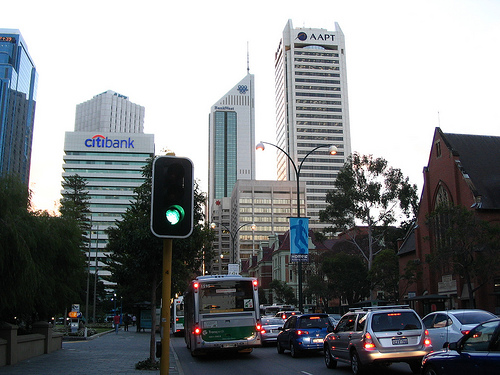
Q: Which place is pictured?
A: It is a city.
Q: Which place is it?
A: It is a city.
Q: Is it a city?
A: Yes, it is a city.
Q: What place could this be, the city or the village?
A: It is the city.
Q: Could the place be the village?
A: No, it is the city.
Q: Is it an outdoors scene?
A: Yes, it is outdoors.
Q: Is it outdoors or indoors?
A: It is outdoors.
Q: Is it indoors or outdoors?
A: It is outdoors.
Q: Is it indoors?
A: No, it is outdoors.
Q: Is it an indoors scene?
A: No, it is outdoors.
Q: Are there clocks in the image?
A: No, there are no clocks.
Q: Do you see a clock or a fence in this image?
A: No, there are no clocks or fences.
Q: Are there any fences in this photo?
A: No, there are no fences.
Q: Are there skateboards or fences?
A: No, there are no fences or skateboards.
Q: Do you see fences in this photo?
A: No, there are no fences.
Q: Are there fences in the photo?
A: No, there are no fences.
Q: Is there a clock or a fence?
A: No, there are no fences or clocks.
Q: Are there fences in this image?
A: No, there are no fences.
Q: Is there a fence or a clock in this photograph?
A: No, there are no fences or clocks.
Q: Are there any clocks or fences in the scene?
A: No, there are no fences or clocks.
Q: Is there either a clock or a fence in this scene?
A: No, there are no fences or clocks.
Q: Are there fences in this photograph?
A: No, there are no fences.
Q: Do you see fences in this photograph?
A: No, there are no fences.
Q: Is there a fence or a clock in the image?
A: No, there are no fences or clocks.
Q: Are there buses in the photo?
A: Yes, there is a bus.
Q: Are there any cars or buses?
A: Yes, there is a bus.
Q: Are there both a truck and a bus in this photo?
A: No, there is a bus but no trucks.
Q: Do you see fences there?
A: No, there are no fences.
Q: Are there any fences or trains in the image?
A: No, there are no fences or trains.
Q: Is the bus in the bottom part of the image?
A: Yes, the bus is in the bottom of the image.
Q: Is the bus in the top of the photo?
A: No, the bus is in the bottom of the image.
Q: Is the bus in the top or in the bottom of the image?
A: The bus is in the bottom of the image.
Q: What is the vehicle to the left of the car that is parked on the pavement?
A: The vehicle is a bus.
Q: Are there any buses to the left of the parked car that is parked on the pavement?
A: Yes, there is a bus to the left of the car.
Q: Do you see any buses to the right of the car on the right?
A: No, the bus is to the left of the car.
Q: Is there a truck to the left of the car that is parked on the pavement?
A: No, there is a bus to the left of the car.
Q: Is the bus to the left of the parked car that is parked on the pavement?
A: Yes, the bus is to the left of the car.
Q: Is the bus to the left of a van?
A: No, the bus is to the left of the car.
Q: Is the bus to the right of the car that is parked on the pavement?
A: No, the bus is to the left of the car.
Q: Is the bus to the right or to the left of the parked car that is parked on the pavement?
A: The bus is to the left of the car.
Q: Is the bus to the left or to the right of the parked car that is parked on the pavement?
A: The bus is to the left of the car.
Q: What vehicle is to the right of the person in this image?
A: The vehicle is a bus.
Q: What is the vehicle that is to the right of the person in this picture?
A: The vehicle is a bus.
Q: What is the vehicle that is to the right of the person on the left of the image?
A: The vehicle is a bus.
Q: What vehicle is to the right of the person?
A: The vehicle is a bus.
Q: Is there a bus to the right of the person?
A: Yes, there is a bus to the right of the person.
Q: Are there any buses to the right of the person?
A: Yes, there is a bus to the right of the person.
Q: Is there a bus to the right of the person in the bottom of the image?
A: Yes, there is a bus to the right of the person.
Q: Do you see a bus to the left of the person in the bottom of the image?
A: No, the bus is to the right of the person.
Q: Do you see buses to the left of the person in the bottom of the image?
A: No, the bus is to the right of the person.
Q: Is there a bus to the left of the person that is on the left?
A: No, the bus is to the right of the person.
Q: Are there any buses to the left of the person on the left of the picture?
A: No, the bus is to the right of the person.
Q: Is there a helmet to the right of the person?
A: No, there is a bus to the right of the person.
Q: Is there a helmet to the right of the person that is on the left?
A: No, there is a bus to the right of the person.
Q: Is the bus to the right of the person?
A: Yes, the bus is to the right of the person.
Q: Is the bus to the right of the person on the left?
A: Yes, the bus is to the right of the person.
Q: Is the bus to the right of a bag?
A: No, the bus is to the right of the person.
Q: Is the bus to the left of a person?
A: No, the bus is to the right of a person.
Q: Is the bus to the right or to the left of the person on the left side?
A: The bus is to the right of the person.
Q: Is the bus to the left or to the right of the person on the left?
A: The bus is to the right of the person.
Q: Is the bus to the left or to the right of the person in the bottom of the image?
A: The bus is to the right of the person.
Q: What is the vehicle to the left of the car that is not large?
A: The vehicle is a bus.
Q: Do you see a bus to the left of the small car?
A: Yes, there is a bus to the left of the car.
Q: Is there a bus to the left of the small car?
A: Yes, there is a bus to the left of the car.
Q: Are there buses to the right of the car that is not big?
A: No, the bus is to the left of the car.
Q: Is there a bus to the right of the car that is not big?
A: No, the bus is to the left of the car.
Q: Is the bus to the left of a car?
A: Yes, the bus is to the left of a car.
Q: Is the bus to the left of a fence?
A: No, the bus is to the left of a car.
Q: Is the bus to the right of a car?
A: No, the bus is to the left of a car.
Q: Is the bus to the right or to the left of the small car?
A: The bus is to the left of the car.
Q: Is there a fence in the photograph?
A: No, there are no fences.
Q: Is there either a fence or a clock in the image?
A: No, there are no fences or clocks.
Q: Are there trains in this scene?
A: No, there are no trains.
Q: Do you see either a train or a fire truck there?
A: No, there are no trains or fire trucks.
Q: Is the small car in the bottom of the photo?
A: Yes, the car is in the bottom of the image.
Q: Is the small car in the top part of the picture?
A: No, the car is in the bottom of the image.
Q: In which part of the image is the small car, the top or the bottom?
A: The car is in the bottom of the image.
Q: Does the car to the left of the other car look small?
A: Yes, the car is small.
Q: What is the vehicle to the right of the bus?
A: The vehicle is a car.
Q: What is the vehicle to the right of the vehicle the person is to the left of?
A: The vehicle is a car.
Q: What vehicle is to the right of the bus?
A: The vehicle is a car.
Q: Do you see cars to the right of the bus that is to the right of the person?
A: Yes, there is a car to the right of the bus.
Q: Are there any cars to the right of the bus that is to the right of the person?
A: Yes, there is a car to the right of the bus.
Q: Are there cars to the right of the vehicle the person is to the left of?
A: Yes, there is a car to the right of the bus.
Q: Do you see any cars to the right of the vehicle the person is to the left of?
A: Yes, there is a car to the right of the bus.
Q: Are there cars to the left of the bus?
A: No, the car is to the right of the bus.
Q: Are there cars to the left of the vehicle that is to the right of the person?
A: No, the car is to the right of the bus.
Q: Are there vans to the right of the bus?
A: No, there is a car to the right of the bus.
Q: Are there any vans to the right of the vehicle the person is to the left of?
A: No, there is a car to the right of the bus.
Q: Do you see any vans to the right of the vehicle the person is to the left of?
A: No, there is a car to the right of the bus.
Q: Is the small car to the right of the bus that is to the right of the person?
A: Yes, the car is to the right of the bus.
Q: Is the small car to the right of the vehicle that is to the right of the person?
A: Yes, the car is to the right of the bus.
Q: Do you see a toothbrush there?
A: No, there are no toothbrushes.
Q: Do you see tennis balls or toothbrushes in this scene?
A: No, there are no toothbrushes or tennis balls.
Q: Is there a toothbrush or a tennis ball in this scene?
A: No, there are no toothbrushes or tennis balls.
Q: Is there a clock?
A: No, there are no clocks.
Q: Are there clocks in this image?
A: No, there are no clocks.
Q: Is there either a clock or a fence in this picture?
A: No, there are no clocks or fences.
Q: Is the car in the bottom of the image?
A: Yes, the car is in the bottom of the image.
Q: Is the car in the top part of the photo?
A: No, the car is in the bottom of the image.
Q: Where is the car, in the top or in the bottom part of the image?
A: The car is in the bottom of the image.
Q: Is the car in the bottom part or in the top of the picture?
A: The car is in the bottom of the image.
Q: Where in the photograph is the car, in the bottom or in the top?
A: The car is in the bottom of the image.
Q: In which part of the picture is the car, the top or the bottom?
A: The car is in the bottom of the image.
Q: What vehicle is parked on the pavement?
A: The vehicle is a car.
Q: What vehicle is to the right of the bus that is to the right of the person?
A: The vehicle is a car.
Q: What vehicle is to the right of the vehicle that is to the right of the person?
A: The vehicle is a car.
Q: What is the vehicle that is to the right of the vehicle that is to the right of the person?
A: The vehicle is a car.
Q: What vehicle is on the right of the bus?
A: The vehicle is a car.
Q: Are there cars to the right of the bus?
A: Yes, there is a car to the right of the bus.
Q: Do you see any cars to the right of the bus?
A: Yes, there is a car to the right of the bus.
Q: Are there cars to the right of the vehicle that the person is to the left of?
A: Yes, there is a car to the right of the bus.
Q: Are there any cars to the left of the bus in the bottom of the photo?
A: No, the car is to the right of the bus.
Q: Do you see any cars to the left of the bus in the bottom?
A: No, the car is to the right of the bus.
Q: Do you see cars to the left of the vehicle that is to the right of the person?
A: No, the car is to the right of the bus.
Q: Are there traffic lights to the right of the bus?
A: No, there is a car to the right of the bus.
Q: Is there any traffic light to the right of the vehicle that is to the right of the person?
A: No, there is a car to the right of the bus.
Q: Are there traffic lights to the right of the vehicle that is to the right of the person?
A: No, there is a car to the right of the bus.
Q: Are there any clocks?
A: No, there are no clocks.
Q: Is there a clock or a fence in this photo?
A: No, there are no clocks or fences.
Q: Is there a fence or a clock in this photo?
A: No, there are no clocks or fences.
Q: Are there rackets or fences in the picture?
A: No, there are no fences or rackets.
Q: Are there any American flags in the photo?
A: No, there are no American flags.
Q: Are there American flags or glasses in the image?
A: No, there are no American flags or glasses.